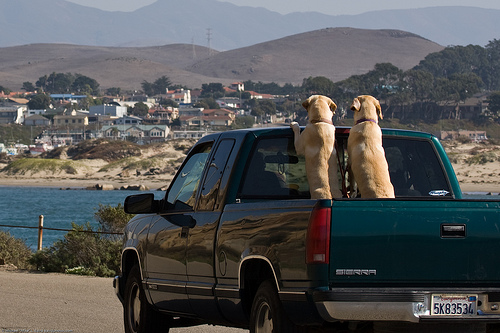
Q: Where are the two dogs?
A: The dogs are in the back of the truck.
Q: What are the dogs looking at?
A: The dogs are looking at mountains in the background.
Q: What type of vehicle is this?
A: Truck.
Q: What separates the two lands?
A: Body of water.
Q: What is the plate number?
A: 5k83534.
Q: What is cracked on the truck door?
A: Window.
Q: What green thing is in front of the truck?
A: Tree.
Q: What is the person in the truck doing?
A: Driving.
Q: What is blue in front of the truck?
A: Water.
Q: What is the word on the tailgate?
A: SIERRA.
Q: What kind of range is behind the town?
A: Mountain.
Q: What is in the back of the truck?
A: Dogs.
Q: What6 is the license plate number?
A: 5K83534.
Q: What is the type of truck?
A: Sierra.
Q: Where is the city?
A: In front of truck.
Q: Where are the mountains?
A: Behind city.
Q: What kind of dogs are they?
A: Labrador Retrievers.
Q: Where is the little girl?
A: No little girl.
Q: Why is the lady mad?
A: No lady.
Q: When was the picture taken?
A: Daytime.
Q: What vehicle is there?
A: A truck.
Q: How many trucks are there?
A: One.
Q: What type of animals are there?
A: Dogs.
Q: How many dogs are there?
A: Two.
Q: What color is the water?
A: Blue.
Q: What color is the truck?
A: Green.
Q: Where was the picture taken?
A: Next to a lake.